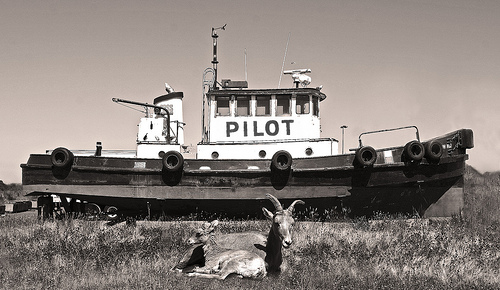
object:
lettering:
[223, 119, 293, 136]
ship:
[21, 23, 476, 225]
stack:
[150, 91, 187, 144]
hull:
[21, 129, 474, 220]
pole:
[208, 30, 222, 88]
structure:
[203, 85, 329, 143]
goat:
[170, 188, 306, 274]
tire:
[355, 145, 376, 166]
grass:
[3, 215, 78, 287]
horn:
[265, 191, 287, 213]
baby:
[184, 219, 268, 280]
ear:
[259, 205, 276, 221]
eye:
[274, 219, 280, 227]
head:
[260, 207, 296, 249]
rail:
[355, 125, 422, 148]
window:
[255, 93, 273, 116]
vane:
[210, 21, 228, 34]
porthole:
[258, 148, 266, 159]